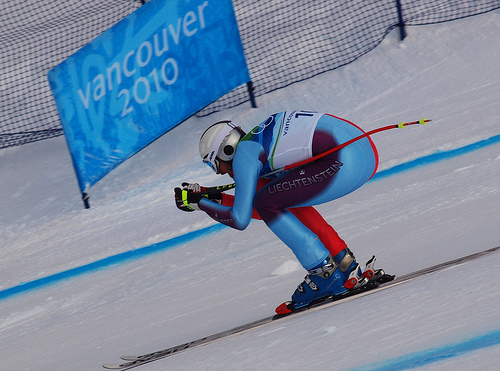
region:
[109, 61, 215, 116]
blue sign saying 2010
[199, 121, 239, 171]
goggles with blue lenses and white strap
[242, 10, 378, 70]
blue checked snow fence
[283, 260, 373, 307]
left blue snowboot with silver buckles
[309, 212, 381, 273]
skier's right pant leg is red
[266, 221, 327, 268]
skier's left pant leg is blue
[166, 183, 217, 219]
light green strap on man's left hand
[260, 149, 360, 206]
says liechtenstein on upper left leg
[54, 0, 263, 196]
blue sign says vancouver 2010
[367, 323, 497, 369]
blue line on the snow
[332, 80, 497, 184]
red stick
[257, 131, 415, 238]
red stick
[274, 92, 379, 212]
red stick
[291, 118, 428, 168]
red stick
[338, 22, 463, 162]
red stick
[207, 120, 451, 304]
red stick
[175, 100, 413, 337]
a skier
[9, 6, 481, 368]
a scene on a slope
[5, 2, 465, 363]
a scene happening at the olympics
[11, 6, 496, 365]
a scene outside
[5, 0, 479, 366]
scene happening during the day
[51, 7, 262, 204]
a blue banner that says VANCOUVER 2010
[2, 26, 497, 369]
a patch of white snow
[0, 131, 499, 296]
a blue line on the snow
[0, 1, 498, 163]
a brown fence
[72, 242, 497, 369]
pair of skies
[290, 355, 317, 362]
the snow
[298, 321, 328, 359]
the snow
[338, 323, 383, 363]
the snow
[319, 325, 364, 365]
the snow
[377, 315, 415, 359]
the snow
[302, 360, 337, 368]
the snow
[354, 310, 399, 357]
the snowthe snow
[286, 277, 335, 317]
edge of a shoe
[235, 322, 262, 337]
edge of a slide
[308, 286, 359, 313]
edge of a shoe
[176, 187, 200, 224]
part of a glove